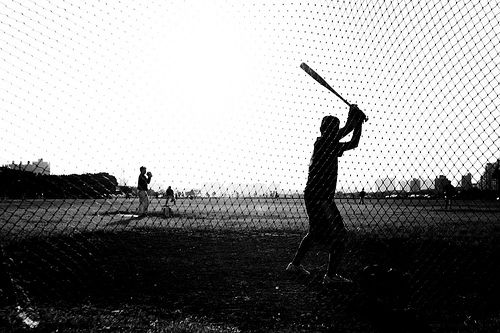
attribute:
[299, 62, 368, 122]
baseball bat — baseball  , air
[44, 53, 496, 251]
fence — black, chain link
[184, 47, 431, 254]
tan colored — closet 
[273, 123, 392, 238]
boy's tshirt — boy's 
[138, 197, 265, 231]
holes — small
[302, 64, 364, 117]
bat — baseball 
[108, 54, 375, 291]
game — baseball 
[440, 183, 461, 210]
baseman — first 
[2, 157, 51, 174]
building — tall, off in the distance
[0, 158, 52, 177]
buildings — tall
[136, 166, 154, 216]
player — baseball 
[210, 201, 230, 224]
holes — small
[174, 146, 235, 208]
holes — small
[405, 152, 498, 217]
buildings — tall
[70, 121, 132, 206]
holes — small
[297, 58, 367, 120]
baseball bat — baseball 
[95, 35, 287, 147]
sky — closet 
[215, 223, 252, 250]
holes — Small 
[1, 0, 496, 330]
holes — small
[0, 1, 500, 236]
holes — small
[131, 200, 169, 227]
base — first 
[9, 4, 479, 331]
photo — baseball game, white , black 